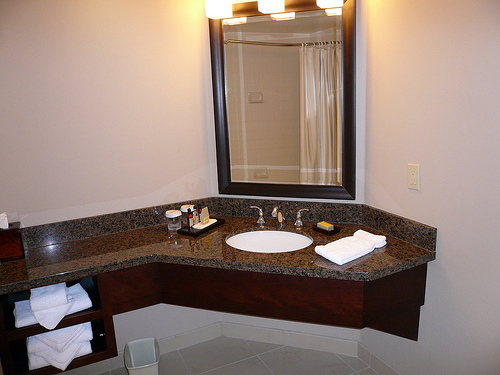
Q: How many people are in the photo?
A: Zero.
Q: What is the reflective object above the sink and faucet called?
A: A mirror.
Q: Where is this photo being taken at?
A: The bathroom.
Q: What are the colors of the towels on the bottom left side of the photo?
A: White.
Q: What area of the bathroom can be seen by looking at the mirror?
A: The shower.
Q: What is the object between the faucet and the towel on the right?
A: Bar soap.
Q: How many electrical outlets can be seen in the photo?
A: Two.